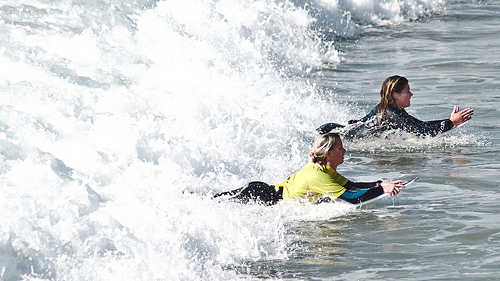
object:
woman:
[208, 132, 407, 209]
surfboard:
[343, 174, 421, 210]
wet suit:
[313, 98, 454, 142]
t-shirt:
[272, 160, 354, 205]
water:
[0, 0, 499, 280]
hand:
[379, 180, 406, 197]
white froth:
[0, 0, 431, 280]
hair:
[306, 131, 339, 167]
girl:
[313, 74, 475, 140]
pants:
[212, 180, 284, 206]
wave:
[0, 0, 499, 280]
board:
[425, 119, 475, 139]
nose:
[341, 146, 349, 153]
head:
[307, 132, 350, 169]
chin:
[337, 158, 351, 165]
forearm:
[352, 185, 384, 205]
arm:
[310, 169, 385, 204]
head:
[378, 76, 413, 107]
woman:
[313, 75, 473, 141]